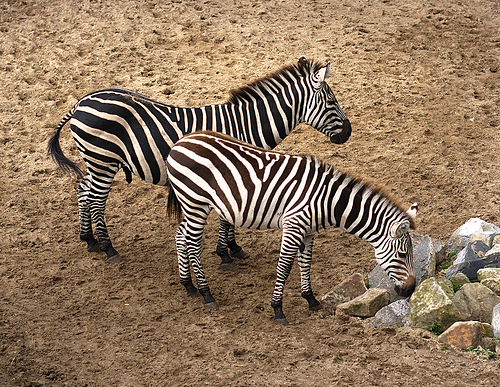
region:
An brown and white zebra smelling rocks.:
[168, 131, 418, 323]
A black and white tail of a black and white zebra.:
[44, 102, 84, 179]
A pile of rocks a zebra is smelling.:
[322, 216, 499, 348]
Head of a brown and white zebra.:
[376, 194, 418, 296]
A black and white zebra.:
[48, 57, 351, 261]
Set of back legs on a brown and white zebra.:
[173, 194, 220, 309]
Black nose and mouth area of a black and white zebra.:
[332, 115, 353, 143]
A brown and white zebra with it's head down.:
[164, 130, 419, 325]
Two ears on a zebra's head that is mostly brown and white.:
[393, 200, 418, 237]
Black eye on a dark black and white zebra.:
[326, 99, 336, 104]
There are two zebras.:
[21, 53, 453, 331]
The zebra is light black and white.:
[160, 135, 413, 310]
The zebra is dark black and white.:
[70, 77, 316, 162]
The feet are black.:
[163, 260, 332, 330]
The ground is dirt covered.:
[32, 285, 242, 384]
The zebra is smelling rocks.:
[373, 253, 431, 315]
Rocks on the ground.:
[315, 220, 498, 342]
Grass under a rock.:
[461, 336, 494, 369]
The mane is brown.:
[328, 161, 417, 225]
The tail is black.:
[38, 128, 82, 177]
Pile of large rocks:
[329, 213, 498, 349]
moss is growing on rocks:
[405, 269, 459, 329]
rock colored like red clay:
[434, 312, 499, 353]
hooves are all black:
[176, 273, 328, 322]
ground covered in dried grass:
[2, 2, 499, 384]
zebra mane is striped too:
[218, 48, 340, 106]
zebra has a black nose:
[320, 109, 358, 150]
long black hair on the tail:
[44, 116, 87, 182]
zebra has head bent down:
[297, 153, 431, 305]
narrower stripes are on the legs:
[81, 166, 330, 298]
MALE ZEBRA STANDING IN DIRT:
[48, 68, 362, 155]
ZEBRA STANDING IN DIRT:
[172, 145, 377, 259]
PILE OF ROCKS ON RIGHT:
[323, 234, 496, 326]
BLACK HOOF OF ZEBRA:
[263, 282, 293, 327]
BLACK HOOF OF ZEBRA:
[300, 286, 325, 307]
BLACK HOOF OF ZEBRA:
[197, 287, 220, 310]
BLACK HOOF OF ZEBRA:
[170, 264, 197, 292]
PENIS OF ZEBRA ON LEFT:
[114, 159, 136, 199]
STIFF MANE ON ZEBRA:
[329, 162, 432, 204]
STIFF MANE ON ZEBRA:
[249, 66, 296, 108]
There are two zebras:
[21, 69, 444, 295]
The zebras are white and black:
[77, 76, 346, 203]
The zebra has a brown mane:
[221, 55, 315, 107]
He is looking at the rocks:
[347, 180, 454, 332]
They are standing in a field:
[34, 24, 459, 357]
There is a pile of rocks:
[326, 175, 493, 352]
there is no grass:
[59, 32, 486, 371]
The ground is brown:
[42, 30, 466, 377]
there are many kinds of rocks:
[408, 212, 493, 357]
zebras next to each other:
[70, 51, 430, 307]